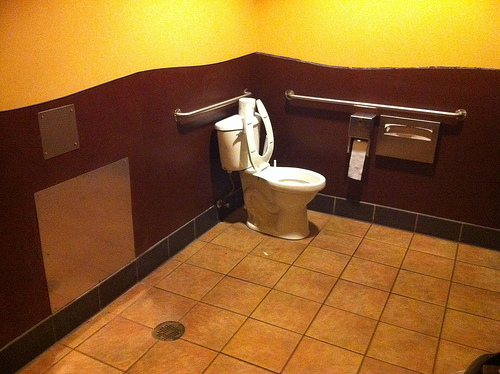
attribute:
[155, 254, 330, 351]
floor — tile, tiled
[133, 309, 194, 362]
drain — floor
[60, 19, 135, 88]
wall — yellow, brown, two toned, bathroom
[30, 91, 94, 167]
plate — silver, small, metal, steel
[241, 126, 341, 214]
toilet — bottom, white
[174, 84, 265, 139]
bar — grab, long, metal, steel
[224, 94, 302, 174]
seat — up, liner, toilet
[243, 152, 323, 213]
closet — water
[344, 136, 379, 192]
paper — toilet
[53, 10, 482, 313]
bathroom — public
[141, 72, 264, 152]
holder — steel